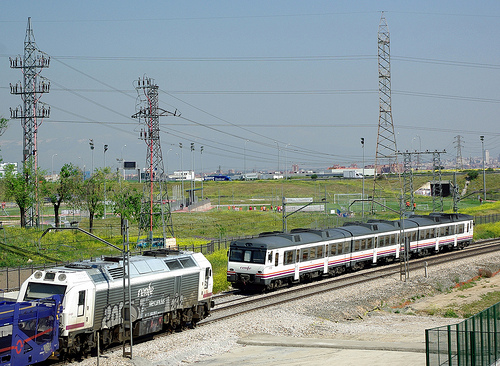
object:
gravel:
[248, 308, 275, 324]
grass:
[17, 210, 159, 269]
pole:
[134, 78, 176, 247]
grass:
[176, 206, 316, 252]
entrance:
[428, 183, 452, 197]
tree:
[35, 162, 83, 231]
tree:
[71, 166, 119, 236]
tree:
[114, 178, 172, 239]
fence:
[424, 301, 499, 365]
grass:
[196, 174, 267, 199]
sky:
[0, 0, 499, 103]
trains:
[227, 212, 475, 295]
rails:
[223, 277, 340, 318]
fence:
[0, 258, 84, 293]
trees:
[0, 158, 54, 229]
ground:
[229, 334, 418, 365]